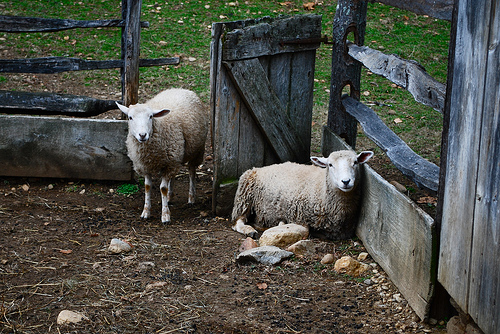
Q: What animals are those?
A: Sheep.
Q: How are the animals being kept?
A: In a pen.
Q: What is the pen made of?
A: Wood.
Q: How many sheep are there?
A: Two.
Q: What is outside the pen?
A: Grass field.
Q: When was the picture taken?
A: Daytime.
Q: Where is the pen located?
A: On a farm.